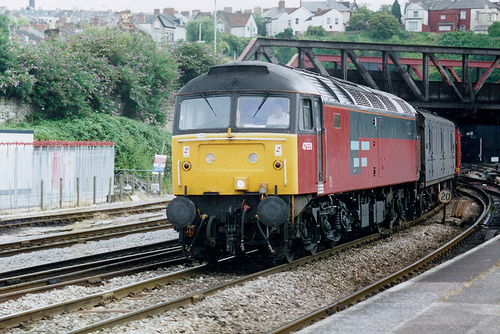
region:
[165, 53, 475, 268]
multicolored train on train tracks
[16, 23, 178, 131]
A cluster of green bushes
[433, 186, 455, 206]
a sign with the number 20 on it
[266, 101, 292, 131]
a man in a train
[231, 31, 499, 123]
a metal bridge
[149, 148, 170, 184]
a white red and blue sign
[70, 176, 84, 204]
a wooden post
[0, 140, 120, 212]
a metal chain link fence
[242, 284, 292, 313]
a pile of rocks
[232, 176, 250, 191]
a bright white light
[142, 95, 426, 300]
this is a train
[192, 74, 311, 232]
this is a vehicle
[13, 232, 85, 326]
these are train tracks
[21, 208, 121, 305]
the tracks are metal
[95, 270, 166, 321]
the tracks are rusted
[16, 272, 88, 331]
these are small stones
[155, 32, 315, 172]
the train is yellow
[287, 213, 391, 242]
these are some wheels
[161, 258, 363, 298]
the wheels are black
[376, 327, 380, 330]
this is a platform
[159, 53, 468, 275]
red, yellow and black train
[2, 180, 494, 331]
rusty metal train tracks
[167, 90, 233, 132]
front window of a train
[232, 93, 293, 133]
front window of a train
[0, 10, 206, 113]
bushy trees with purple flowers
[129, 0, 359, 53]
cluster of white homes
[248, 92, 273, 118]
train's wind shield wiper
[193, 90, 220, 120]
train's wind shield wiper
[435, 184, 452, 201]
short red framed white sign with a black 20 on it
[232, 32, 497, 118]
red and black metal bridge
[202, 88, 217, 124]
windshield wiper on a train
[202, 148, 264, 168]
head lights on a train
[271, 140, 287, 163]
sticker on a train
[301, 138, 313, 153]
number on a train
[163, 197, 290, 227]
bumper on a train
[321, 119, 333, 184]
hand rail on a train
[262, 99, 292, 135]
operator driving a train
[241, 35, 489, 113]
bridge over a train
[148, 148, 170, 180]
sign in the yard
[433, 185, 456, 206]
Number 20 on a pole